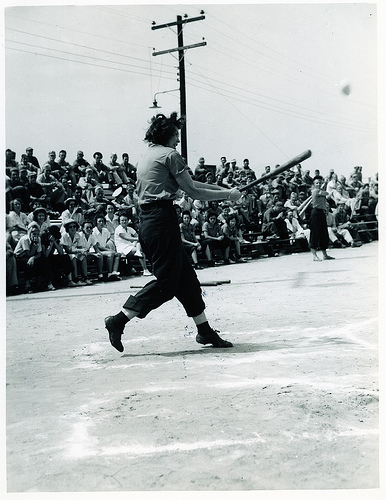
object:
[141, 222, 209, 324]
legs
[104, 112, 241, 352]
woman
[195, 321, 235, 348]
foot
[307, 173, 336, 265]
woman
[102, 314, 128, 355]
foot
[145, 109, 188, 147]
head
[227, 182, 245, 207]
hand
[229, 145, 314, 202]
bat